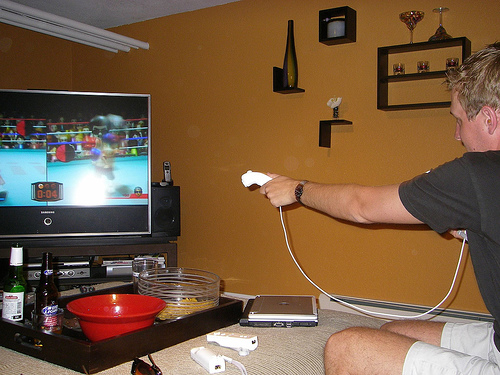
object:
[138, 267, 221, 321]
bowl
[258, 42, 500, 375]
man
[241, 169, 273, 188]
controller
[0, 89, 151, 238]
game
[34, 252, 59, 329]
bottle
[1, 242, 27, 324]
beer bottle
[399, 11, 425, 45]
glasses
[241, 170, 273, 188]
game controller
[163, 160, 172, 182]
phone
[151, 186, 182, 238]
speaker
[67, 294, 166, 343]
red bowl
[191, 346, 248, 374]
controller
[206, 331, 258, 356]
controller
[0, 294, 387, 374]
bed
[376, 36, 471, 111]
shelf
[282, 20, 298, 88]
vase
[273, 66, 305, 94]
shelf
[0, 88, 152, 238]
television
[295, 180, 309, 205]
watch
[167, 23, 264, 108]
wall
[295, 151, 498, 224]
arm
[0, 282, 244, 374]
drawer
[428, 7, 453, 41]
glasses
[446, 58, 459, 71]
glasses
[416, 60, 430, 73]
glasses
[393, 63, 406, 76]
glasses